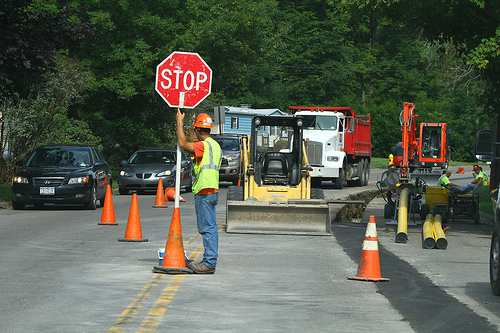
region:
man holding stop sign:
[127, 48, 219, 272]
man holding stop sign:
[152, 40, 233, 281]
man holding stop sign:
[137, 47, 228, 288]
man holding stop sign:
[120, 39, 225, 283]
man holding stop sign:
[129, 50, 229, 284]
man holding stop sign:
[139, 36, 238, 330]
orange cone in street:
[354, 210, 388, 290]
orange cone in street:
[148, 205, 195, 280]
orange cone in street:
[117, 186, 144, 251]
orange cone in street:
[115, 185, 150, 247]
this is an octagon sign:
[146, 38, 234, 230]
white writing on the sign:
[140, 47, 235, 119]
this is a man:
[170, 102, 241, 279]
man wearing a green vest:
[182, 127, 232, 197]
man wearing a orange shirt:
[179, 130, 228, 191]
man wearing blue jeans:
[190, 170, 225, 262]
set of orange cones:
[91, 174, 213, 290]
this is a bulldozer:
[199, 77, 343, 247]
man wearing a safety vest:
[189, 141, 229, 204]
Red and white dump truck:
[287, 95, 382, 172]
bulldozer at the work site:
[225, 100, 325, 245]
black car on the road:
[12, 137, 114, 212]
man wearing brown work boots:
[184, 243, 214, 283]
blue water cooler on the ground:
[156, 243, 181, 268]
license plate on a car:
[38, 185, 58, 196]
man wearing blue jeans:
[186, 190, 228, 267]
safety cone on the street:
[343, 213, 388, 289]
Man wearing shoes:
[182, 255, 218, 277]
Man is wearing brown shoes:
[182, 255, 213, 276]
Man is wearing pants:
[190, 184, 224, 268]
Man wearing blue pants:
[192, 187, 222, 267]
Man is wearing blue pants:
[192, 183, 224, 269]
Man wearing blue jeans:
[191, 186, 221, 267]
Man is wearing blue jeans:
[193, 190, 220, 269]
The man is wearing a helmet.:
[191, 112, 219, 142]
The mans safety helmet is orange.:
[188, 112, 225, 142]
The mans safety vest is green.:
[175, 129, 226, 196]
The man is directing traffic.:
[145, 42, 239, 288]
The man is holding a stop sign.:
[146, 48, 228, 153]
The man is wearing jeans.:
[188, 183, 233, 283]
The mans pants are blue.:
[175, 180, 230, 292]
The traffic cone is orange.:
[95, 178, 121, 235]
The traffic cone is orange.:
[119, 188, 153, 250]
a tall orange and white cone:
[351, 214, 392, 288]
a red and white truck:
[289, 100, 377, 187]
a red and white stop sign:
[148, 50, 213, 213]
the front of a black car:
[11, 137, 113, 213]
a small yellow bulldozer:
[226, 106, 333, 237]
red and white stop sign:
[141, 44, 220, 109]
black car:
[24, 136, 100, 228]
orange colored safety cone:
[156, 194, 193, 278]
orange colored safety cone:
[117, 179, 145, 254]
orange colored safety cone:
[88, 181, 123, 234]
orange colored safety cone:
[151, 176, 171, 208]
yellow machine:
[236, 119, 318, 241]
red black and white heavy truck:
[303, 92, 381, 189]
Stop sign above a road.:
[152, 45, 215, 114]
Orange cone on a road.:
[161, 202, 194, 276]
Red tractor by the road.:
[390, 99, 453, 184]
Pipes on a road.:
[393, 182, 455, 259]